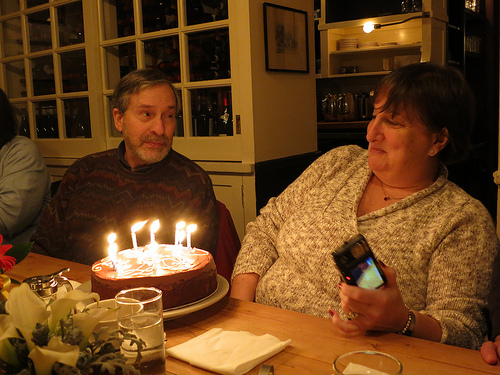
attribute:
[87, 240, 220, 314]
cake — chocolate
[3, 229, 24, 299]
flower — red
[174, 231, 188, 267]
candle — burning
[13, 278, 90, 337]
flower — white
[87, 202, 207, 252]
candle — burning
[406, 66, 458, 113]
hair — short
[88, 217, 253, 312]
cake — chocolate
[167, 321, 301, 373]
napking — white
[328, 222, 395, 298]
camera — Black digital 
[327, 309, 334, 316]
fingernail — dark red, painted 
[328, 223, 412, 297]
camera — black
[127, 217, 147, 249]
candle — burning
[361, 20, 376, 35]
bulb — light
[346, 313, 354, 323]
ring — shiny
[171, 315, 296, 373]
napkin — white, folded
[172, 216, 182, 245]
candle — burning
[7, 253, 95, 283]
flowers — white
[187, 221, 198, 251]
candle — burning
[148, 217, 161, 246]
candle — burning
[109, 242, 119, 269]
candle — burning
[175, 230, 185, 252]
candle — burning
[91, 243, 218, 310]
cake — chocolate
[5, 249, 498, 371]
table — wooden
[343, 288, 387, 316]
badsentence — painted 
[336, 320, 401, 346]
badsentence — painted 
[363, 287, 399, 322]
badsentence — painted 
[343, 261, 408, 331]
hand — woman's 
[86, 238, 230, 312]
cake — chocolate